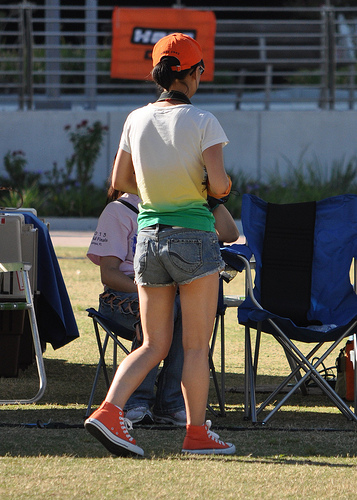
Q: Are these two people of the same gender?
A: Yes, all the people are female.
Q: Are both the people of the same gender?
A: Yes, all the people are female.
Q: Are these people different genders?
A: No, all the people are female.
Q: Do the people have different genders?
A: No, all the people are female.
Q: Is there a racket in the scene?
A: No, there are no rackets.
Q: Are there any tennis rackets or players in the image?
A: No, there are no tennis rackets or players.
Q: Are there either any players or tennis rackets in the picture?
A: No, there are no tennis rackets or players.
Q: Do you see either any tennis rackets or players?
A: No, there are no tennis rackets or players.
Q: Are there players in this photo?
A: No, there are no players.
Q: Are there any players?
A: No, there are no players.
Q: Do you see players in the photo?
A: No, there are no players.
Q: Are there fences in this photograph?
A: Yes, there is a fence.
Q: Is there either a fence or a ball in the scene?
A: Yes, there is a fence.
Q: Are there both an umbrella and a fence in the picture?
A: No, there is a fence but no umbrellas.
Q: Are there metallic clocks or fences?
A: Yes, there is a metal fence.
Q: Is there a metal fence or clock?
A: Yes, there is a metal fence.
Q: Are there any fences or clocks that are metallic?
A: Yes, the fence is metallic.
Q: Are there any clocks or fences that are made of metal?
A: Yes, the fence is made of metal.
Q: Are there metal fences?
A: Yes, there is a metal fence.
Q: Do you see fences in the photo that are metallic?
A: Yes, there is a fence that is metallic.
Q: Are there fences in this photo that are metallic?
A: Yes, there is a fence that is metallic.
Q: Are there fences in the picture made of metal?
A: Yes, there is a fence that is made of metal.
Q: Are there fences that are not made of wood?
A: Yes, there is a fence that is made of metal.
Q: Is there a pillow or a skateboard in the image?
A: No, there are no skateboards or pillows.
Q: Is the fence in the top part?
A: Yes, the fence is in the top of the image.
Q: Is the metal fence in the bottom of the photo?
A: No, the fence is in the top of the image.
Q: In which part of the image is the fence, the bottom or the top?
A: The fence is in the top of the image.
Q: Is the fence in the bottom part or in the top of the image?
A: The fence is in the top of the image.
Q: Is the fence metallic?
A: Yes, the fence is metallic.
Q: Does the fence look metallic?
A: Yes, the fence is metallic.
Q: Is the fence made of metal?
A: Yes, the fence is made of metal.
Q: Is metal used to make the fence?
A: Yes, the fence is made of metal.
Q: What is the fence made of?
A: The fence is made of metal.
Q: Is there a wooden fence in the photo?
A: No, there is a fence but it is metallic.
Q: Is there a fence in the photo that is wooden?
A: No, there is a fence but it is metallic.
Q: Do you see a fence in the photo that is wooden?
A: No, there is a fence but it is metallic.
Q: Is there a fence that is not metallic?
A: No, there is a fence but it is metallic.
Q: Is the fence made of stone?
A: No, the fence is made of metal.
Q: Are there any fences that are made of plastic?
A: No, there is a fence but it is made of metal.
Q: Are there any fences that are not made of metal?
A: No, there is a fence but it is made of metal.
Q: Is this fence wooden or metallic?
A: The fence is metallic.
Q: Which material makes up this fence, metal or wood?
A: The fence is made of metal.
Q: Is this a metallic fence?
A: Yes, this is a metallic fence.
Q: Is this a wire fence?
A: No, this is a metallic fence.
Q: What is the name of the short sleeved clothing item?
A: The clothing item is a t-shirt.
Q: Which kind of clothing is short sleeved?
A: The clothing is a t-shirt.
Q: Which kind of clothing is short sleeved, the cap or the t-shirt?
A: The t-shirt is short sleeved.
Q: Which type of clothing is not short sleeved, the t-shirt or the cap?
A: The cap is not short sleeved.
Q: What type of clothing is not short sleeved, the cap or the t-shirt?
A: The cap is not short sleeved.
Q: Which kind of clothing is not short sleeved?
A: The clothing is a cap.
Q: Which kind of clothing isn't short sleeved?
A: The clothing is a cap.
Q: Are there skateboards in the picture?
A: No, there are no skateboards.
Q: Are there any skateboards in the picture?
A: No, there are no skateboards.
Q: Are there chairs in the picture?
A: Yes, there is a chair.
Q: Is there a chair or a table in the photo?
A: Yes, there is a chair.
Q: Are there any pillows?
A: No, there are no pillows.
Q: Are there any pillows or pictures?
A: No, there are no pillows or pictures.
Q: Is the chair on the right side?
A: Yes, the chair is on the right of the image.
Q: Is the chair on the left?
A: No, the chair is on the right of the image.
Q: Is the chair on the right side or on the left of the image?
A: The chair is on the right of the image.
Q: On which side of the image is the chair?
A: The chair is on the right of the image.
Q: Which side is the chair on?
A: The chair is on the right of the image.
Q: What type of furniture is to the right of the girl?
A: The piece of furniture is a chair.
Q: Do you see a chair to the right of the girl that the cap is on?
A: Yes, there is a chair to the right of the girl.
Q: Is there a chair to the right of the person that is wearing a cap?
A: Yes, there is a chair to the right of the girl.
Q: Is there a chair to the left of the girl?
A: No, the chair is to the right of the girl.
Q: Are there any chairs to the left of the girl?
A: No, the chair is to the right of the girl.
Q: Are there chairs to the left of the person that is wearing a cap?
A: No, the chair is to the right of the girl.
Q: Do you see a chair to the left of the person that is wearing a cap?
A: No, the chair is to the right of the girl.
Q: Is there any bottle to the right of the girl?
A: No, there is a chair to the right of the girl.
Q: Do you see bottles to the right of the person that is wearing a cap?
A: No, there is a chair to the right of the girl.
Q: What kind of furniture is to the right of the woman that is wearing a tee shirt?
A: The piece of furniture is a chair.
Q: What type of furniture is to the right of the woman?
A: The piece of furniture is a chair.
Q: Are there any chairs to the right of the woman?
A: Yes, there is a chair to the right of the woman.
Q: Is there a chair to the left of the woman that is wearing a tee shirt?
A: No, the chair is to the right of the woman.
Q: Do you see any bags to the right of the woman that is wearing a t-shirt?
A: No, there is a chair to the right of the woman.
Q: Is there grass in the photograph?
A: Yes, there is grass.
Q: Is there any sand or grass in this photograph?
A: Yes, there is grass.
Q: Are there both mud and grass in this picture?
A: No, there is grass but no mud.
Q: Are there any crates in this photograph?
A: No, there are no crates.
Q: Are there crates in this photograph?
A: No, there are no crates.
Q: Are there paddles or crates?
A: No, there are no crates or paddles.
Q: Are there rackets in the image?
A: No, there are no rackets.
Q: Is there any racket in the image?
A: No, there are no rackets.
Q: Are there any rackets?
A: No, there are no rackets.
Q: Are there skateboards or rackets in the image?
A: No, there are no rackets or skateboards.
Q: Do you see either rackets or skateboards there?
A: No, there are no rackets or skateboards.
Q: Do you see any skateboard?
A: No, there are no skateboards.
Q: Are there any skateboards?
A: No, there are no skateboards.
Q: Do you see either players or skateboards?
A: No, there are no skateboards or players.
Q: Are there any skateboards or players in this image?
A: No, there are no skateboards or players.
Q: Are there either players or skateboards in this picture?
A: No, there are no skateboards or players.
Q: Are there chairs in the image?
A: Yes, there is a chair.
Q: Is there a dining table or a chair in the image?
A: Yes, there is a chair.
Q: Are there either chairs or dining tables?
A: Yes, there is a chair.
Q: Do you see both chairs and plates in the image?
A: No, there is a chair but no plates.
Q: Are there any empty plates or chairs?
A: Yes, there is an empty chair.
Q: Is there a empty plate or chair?
A: Yes, there is an empty chair.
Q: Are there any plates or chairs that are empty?
A: Yes, the chair is empty.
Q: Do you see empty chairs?
A: Yes, there is an empty chair.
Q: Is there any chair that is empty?
A: Yes, there is a chair that is empty.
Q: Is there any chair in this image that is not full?
A: Yes, there is a empty chair.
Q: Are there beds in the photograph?
A: No, there are no beds.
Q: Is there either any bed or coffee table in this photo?
A: No, there are no beds or coffee tables.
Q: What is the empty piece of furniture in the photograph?
A: The piece of furniture is a chair.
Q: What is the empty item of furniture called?
A: The piece of furniture is a chair.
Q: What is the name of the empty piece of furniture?
A: The piece of furniture is a chair.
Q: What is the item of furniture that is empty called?
A: The piece of furniture is a chair.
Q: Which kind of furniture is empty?
A: The furniture is a chair.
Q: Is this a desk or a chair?
A: This is a chair.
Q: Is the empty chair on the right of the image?
A: Yes, the chair is on the right of the image.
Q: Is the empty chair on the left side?
A: No, the chair is on the right of the image.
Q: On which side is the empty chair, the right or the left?
A: The chair is on the right of the image.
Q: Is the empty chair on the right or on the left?
A: The chair is on the right of the image.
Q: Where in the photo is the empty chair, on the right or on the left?
A: The chair is on the right of the image.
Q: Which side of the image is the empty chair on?
A: The chair is on the right of the image.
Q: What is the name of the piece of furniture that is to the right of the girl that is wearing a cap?
A: The piece of furniture is a chair.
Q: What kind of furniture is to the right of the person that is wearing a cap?
A: The piece of furniture is a chair.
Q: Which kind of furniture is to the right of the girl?
A: The piece of furniture is a chair.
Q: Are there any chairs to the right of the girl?
A: Yes, there is a chair to the right of the girl.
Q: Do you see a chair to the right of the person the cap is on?
A: Yes, there is a chair to the right of the girl.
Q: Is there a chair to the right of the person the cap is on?
A: Yes, there is a chair to the right of the girl.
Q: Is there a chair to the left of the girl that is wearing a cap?
A: No, the chair is to the right of the girl.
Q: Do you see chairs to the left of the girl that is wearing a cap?
A: No, the chair is to the right of the girl.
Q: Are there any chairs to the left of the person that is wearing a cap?
A: No, the chair is to the right of the girl.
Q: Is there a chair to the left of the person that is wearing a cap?
A: No, the chair is to the right of the girl.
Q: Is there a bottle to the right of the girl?
A: No, there is a chair to the right of the girl.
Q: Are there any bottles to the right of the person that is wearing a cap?
A: No, there is a chair to the right of the girl.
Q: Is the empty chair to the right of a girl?
A: Yes, the chair is to the right of a girl.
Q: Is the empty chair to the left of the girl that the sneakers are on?
A: No, the chair is to the right of the girl.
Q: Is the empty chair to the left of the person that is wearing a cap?
A: No, the chair is to the right of the girl.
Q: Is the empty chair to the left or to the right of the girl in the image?
A: The chair is to the right of the girl.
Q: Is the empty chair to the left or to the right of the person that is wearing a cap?
A: The chair is to the right of the girl.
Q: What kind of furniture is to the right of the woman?
A: The piece of furniture is a chair.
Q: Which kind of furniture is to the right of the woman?
A: The piece of furniture is a chair.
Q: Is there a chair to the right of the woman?
A: Yes, there is a chair to the right of the woman.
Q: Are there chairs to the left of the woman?
A: No, the chair is to the right of the woman.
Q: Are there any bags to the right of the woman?
A: No, there is a chair to the right of the woman.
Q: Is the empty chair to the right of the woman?
A: Yes, the chair is to the right of the woman.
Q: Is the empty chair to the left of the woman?
A: No, the chair is to the right of the woman.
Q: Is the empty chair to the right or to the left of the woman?
A: The chair is to the right of the woman.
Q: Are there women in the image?
A: Yes, there is a woman.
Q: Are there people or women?
A: Yes, there is a woman.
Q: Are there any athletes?
A: No, there are no athletes.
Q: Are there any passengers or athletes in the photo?
A: No, there are no athletes or passengers.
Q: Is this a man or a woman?
A: This is a woman.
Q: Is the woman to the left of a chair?
A: Yes, the woman is to the left of a chair.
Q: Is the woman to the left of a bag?
A: No, the woman is to the left of a chair.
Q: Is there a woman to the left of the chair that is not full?
A: Yes, there is a woman to the left of the chair.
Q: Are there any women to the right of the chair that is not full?
A: No, the woman is to the left of the chair.